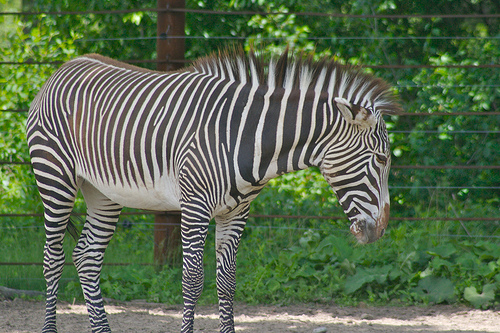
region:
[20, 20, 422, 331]
zebra standing on ground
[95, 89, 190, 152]
balck and white zebra fur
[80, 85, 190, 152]
striped pattern on zebra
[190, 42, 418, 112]
black and white zebra mane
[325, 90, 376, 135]
zebra ear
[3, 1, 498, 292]
black wire fence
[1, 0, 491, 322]
green trees and shrubs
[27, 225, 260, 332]
four zebra legs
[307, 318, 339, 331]
rock on dirt ground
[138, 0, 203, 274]
metal fence support pole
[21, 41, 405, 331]
a black and white zebra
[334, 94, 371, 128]
a zebra ear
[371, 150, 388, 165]
the eye of a zebra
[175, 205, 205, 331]
a zebra's long leg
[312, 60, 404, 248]
the head of a black and white zebra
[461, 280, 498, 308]
a large green leaf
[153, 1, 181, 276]
a wooden pole behind a zebra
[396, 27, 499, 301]
lush green bushy area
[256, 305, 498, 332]
an area of dirt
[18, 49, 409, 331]
a large zebra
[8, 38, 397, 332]
this is a zebra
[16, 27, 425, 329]
a single zebra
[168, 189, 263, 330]
this is the front leg of a zebra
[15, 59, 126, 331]
this is the hind leg of a zebra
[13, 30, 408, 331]
the zebra has stripes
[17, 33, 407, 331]
the zebra has black and white stripes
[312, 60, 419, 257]
this is the zebra's head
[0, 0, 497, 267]
there is a red fence in the background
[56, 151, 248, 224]
the stomach of the zebra is white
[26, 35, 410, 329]
a zebra in a zoo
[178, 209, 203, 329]
leg of a zebra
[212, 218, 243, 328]
leg of a zebra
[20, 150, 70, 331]
leg of a zebra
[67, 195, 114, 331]
leg of a zebra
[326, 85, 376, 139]
black and white ear of zebra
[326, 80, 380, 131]
black and white ear of zebra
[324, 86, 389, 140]
black and white ear of zebra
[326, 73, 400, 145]
black and white ear of zebra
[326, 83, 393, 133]
black and white ear of zebra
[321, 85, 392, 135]
black and white ear of zebra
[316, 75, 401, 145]
black and white ear of zebra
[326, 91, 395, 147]
black and white ear of zebra